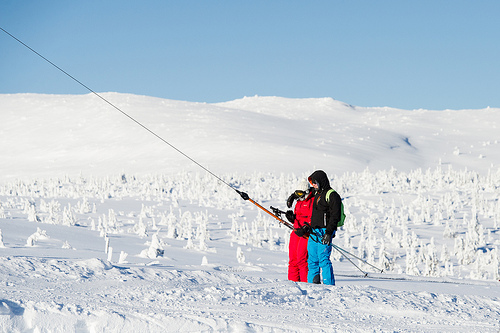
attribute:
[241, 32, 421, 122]
clouds — white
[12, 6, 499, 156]
sky — blue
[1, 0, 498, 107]
sky — blue, white,  blue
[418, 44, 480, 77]
clouds — white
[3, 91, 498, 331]
snow — white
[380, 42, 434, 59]
sky — blue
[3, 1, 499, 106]
clouds — white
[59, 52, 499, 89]
clouds — white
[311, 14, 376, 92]
sky — blue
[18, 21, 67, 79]
clouds — white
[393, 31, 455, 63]
sky — blue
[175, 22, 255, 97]
sky — blue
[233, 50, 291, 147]
clouds — white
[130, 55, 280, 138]
sky — blue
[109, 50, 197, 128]
clouds — white 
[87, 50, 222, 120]
clouds — white 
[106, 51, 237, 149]
clouds — white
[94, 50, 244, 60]
clouds — white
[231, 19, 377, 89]
clouds — white